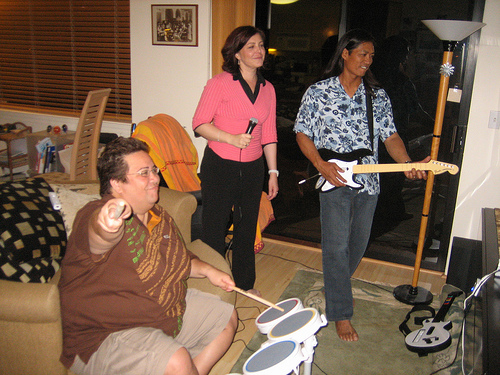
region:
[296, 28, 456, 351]
The woman is holding a guitar.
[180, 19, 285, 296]
The woman is holding a microphone.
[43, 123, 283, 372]
The woman is holding a drumstick.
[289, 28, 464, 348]
The woman is barefoot.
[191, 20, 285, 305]
The woman is barefoot.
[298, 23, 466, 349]
The woman is smiling.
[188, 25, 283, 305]
The woman is smiling.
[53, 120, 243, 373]
The woman is smiling.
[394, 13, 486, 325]
The floor lamp has a white shade.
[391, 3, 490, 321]
A silver bow is on the pole of the floor lamp.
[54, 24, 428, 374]
people playing video games together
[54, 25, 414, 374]
video game is of people singing and playing instruments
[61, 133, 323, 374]
person is playing the drums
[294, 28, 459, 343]
man is playing a guitar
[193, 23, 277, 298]
woman is singing in microphone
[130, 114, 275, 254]
sheet or blanket draped over chair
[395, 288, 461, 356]
second guitar is laying on the floor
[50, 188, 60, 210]
wii remote on arm of chair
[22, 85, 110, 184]
very long backed wooden chair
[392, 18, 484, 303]
very tall light in living room turned off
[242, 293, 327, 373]
electronic drums on stand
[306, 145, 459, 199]
black and white electric guitar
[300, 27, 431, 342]
young man with electric guitar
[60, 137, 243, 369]
person sitting on edge of chair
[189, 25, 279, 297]
young woman with microphone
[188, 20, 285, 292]
young woman wearing pink sweater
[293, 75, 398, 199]
blue and white shirt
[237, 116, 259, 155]
microphone being held by young woman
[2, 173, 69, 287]
black pillow with gold and tan blocks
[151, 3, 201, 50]
framed picture on wall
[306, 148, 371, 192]
Black and white guitar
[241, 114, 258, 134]
Black and silver microphone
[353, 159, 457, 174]
Tan head stock on guitar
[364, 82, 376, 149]
Long black guitar strap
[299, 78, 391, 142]
Light blue shirt with dark blue pattern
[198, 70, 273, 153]
Pink sweater with stripes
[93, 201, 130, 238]
hand pointing with drumstick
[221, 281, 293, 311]
drumstick hitting grey drum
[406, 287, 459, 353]
White and black guitar on floor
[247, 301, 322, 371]
White and grey drum set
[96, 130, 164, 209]
the head of a woman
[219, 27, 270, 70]
the head of a woman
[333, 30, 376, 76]
the head of a man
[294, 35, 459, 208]
a man holding a guitar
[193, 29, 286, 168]
a woman holding a microphone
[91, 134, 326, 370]
a woman playing the drums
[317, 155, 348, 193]
a hand of a man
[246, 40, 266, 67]
the face of a woman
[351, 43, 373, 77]
the face of a man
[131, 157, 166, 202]
the face of a woman